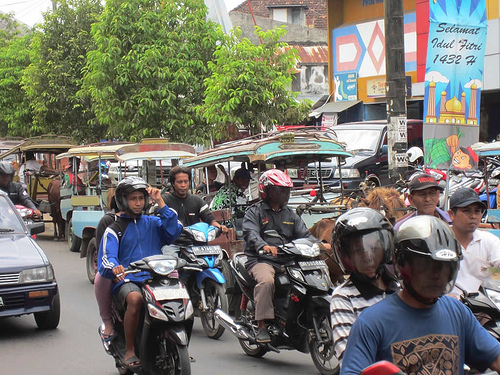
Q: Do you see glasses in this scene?
A: No, there are no glasses.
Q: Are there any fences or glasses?
A: No, there are no glasses or fences.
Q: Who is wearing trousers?
A: The man is wearing trousers.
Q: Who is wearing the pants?
A: The man is wearing trousers.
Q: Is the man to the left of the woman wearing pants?
A: Yes, the man is wearing pants.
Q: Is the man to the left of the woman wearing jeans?
A: No, the man is wearing pants.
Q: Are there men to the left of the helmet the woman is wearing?
A: Yes, there is a man to the left of the helmet.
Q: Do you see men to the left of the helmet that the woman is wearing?
A: Yes, there is a man to the left of the helmet.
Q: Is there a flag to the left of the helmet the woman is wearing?
A: No, there is a man to the left of the helmet.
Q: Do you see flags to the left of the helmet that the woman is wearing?
A: No, there is a man to the left of the helmet.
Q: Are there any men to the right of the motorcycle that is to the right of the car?
A: Yes, there is a man to the right of the motorcycle.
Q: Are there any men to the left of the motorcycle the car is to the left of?
A: No, the man is to the right of the motorcycle.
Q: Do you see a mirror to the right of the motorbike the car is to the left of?
A: No, there is a man to the right of the motorbike.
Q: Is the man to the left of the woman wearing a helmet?
A: Yes, the man is wearing a helmet.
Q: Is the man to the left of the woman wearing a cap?
A: No, the man is wearing a helmet.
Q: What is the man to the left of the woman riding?
A: The man is riding a motorcycle.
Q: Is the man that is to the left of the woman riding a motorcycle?
A: Yes, the man is riding a motorcycle.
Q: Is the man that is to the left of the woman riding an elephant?
A: No, the man is riding a motorcycle.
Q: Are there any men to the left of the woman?
A: Yes, there is a man to the left of the woman.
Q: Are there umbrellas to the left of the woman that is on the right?
A: No, there is a man to the left of the woman.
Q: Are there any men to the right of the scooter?
A: Yes, there is a man to the right of the scooter.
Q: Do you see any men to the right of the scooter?
A: Yes, there is a man to the right of the scooter.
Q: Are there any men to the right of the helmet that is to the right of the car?
A: Yes, there is a man to the right of the helmet.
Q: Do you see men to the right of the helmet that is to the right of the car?
A: Yes, there is a man to the right of the helmet.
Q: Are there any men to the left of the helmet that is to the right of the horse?
A: No, the man is to the right of the helmet.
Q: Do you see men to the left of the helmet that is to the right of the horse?
A: No, the man is to the right of the helmet.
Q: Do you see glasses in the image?
A: No, there are no glasses.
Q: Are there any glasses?
A: No, there are no glasses.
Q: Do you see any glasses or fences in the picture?
A: No, there are no glasses or fences.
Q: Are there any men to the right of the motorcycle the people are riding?
A: Yes, there is a man to the right of the motorbike.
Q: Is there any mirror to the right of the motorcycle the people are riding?
A: No, there is a man to the right of the motorbike.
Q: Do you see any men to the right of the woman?
A: Yes, there is a man to the right of the woman.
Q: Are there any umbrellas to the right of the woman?
A: No, there is a man to the right of the woman.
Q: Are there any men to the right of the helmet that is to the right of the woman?
A: Yes, there is a man to the right of the helmet.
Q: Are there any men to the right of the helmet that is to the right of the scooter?
A: Yes, there is a man to the right of the helmet.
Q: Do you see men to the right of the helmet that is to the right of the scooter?
A: Yes, there is a man to the right of the helmet.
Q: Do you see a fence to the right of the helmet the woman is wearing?
A: No, there is a man to the right of the helmet.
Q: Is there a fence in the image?
A: No, there are no fences.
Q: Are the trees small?
A: Yes, the trees are small.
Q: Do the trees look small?
A: Yes, the trees are small.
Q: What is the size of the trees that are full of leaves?
A: The trees are small.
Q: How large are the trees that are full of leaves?
A: The trees are small.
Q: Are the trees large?
A: No, the trees are small.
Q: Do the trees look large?
A: No, the trees are small.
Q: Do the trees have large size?
A: No, the trees are small.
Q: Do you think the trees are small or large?
A: The trees are small.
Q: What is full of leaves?
A: The trees are full of leaves.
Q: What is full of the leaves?
A: The trees are full of leaves.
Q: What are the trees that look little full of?
A: The trees are full of leaves.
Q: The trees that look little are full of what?
A: The trees are full of leaves.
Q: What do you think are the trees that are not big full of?
A: The trees are full of leaves.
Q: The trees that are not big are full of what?
A: The trees are full of leaves.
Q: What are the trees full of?
A: The trees are full of leaves.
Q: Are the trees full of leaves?
A: Yes, the trees are full of leaves.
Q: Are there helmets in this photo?
A: Yes, there is a helmet.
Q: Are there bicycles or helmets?
A: Yes, there is a helmet.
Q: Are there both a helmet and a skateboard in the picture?
A: No, there is a helmet but no skateboards.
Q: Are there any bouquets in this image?
A: No, there are no bouquets.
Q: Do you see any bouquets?
A: No, there are no bouquets.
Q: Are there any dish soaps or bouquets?
A: No, there are no bouquets or dish soaps.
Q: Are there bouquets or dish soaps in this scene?
A: No, there are no bouquets or dish soaps.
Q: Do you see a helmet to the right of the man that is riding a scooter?
A: Yes, there is a helmet to the right of the man.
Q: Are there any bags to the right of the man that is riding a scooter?
A: No, there is a helmet to the right of the man.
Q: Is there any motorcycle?
A: Yes, there is a motorcycle.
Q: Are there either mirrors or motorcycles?
A: Yes, there is a motorcycle.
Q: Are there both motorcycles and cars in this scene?
A: Yes, there are both a motorcycle and a car.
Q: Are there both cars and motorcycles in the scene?
A: Yes, there are both a motorcycle and a car.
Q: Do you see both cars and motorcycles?
A: Yes, there are both a motorcycle and a car.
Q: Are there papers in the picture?
A: No, there are no papers.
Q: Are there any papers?
A: No, there are no papers.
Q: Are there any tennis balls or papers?
A: No, there are no papers or tennis balls.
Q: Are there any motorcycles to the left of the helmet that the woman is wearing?
A: Yes, there is a motorcycle to the left of the helmet.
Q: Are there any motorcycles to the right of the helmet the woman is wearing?
A: No, the motorcycle is to the left of the helmet.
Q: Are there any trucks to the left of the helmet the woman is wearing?
A: No, there is a motorcycle to the left of the helmet.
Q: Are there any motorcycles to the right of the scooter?
A: Yes, there is a motorcycle to the right of the scooter.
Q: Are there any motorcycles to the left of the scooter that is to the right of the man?
A: No, the motorcycle is to the right of the scooter.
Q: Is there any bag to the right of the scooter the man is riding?
A: No, there is a motorcycle to the right of the scooter.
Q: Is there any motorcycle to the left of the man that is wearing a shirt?
A: Yes, there is a motorcycle to the left of the man.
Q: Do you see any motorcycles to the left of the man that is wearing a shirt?
A: Yes, there is a motorcycle to the left of the man.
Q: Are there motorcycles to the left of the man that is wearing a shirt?
A: Yes, there is a motorcycle to the left of the man.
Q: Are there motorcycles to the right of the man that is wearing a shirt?
A: No, the motorcycle is to the left of the man.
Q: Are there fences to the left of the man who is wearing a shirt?
A: No, there is a motorcycle to the left of the man.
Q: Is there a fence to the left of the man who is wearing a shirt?
A: No, there is a motorcycle to the left of the man.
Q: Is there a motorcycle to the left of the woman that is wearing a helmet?
A: Yes, there is a motorcycle to the left of the woman.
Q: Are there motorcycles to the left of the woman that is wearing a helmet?
A: Yes, there is a motorcycle to the left of the woman.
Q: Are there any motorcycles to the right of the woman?
A: No, the motorcycle is to the left of the woman.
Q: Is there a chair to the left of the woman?
A: No, there is a motorcycle to the left of the woman.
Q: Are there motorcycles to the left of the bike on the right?
A: Yes, there is a motorcycle to the left of the bike.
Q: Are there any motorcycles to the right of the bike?
A: No, the motorcycle is to the left of the bike.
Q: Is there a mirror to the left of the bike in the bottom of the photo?
A: No, there is a motorcycle to the left of the bike.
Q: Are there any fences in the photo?
A: No, there are no fences.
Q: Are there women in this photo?
A: Yes, there is a woman.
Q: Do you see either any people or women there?
A: Yes, there is a woman.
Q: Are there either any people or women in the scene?
A: Yes, there is a woman.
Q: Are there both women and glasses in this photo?
A: No, there is a woman but no glasses.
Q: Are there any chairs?
A: No, there are no chairs.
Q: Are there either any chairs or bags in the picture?
A: No, there are no chairs or bags.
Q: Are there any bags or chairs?
A: No, there are no chairs or bags.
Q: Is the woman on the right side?
A: Yes, the woman is on the right of the image.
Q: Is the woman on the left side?
A: No, the woman is on the right of the image.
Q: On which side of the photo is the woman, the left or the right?
A: The woman is on the right of the image.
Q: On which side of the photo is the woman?
A: The woman is on the right of the image.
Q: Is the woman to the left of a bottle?
A: No, the woman is to the left of the helmet.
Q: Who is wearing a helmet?
A: The woman is wearing a helmet.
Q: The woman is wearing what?
A: The woman is wearing a helmet.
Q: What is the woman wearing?
A: The woman is wearing a helmet.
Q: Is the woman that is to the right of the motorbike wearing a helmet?
A: Yes, the woman is wearing a helmet.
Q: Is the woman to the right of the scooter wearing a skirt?
A: No, the woman is wearing a helmet.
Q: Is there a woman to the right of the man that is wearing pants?
A: Yes, there is a woman to the right of the man.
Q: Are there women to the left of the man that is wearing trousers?
A: No, the woman is to the right of the man.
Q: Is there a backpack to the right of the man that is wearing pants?
A: No, there is a woman to the right of the man.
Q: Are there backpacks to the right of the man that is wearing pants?
A: No, there is a woman to the right of the man.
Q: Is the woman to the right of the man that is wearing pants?
A: Yes, the woman is to the right of the man.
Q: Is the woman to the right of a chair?
A: No, the woman is to the right of the man.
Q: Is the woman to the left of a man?
A: No, the woman is to the right of a man.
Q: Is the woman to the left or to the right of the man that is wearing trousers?
A: The woman is to the right of the man.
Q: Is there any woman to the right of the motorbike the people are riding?
A: Yes, there is a woman to the right of the motorbike.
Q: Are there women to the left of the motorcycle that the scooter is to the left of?
A: No, the woman is to the right of the motorbike.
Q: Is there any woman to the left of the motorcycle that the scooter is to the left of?
A: No, the woman is to the right of the motorbike.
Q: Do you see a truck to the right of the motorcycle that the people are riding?
A: No, there is a woman to the right of the motorbike.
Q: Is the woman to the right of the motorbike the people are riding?
A: Yes, the woman is to the right of the motorbike.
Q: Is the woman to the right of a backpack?
A: No, the woman is to the right of the motorbike.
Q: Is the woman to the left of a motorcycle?
A: No, the woman is to the right of a motorcycle.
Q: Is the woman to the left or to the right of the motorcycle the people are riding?
A: The woman is to the right of the motorcycle.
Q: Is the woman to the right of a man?
A: No, the woman is to the left of a man.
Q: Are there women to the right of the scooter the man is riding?
A: Yes, there is a woman to the right of the scooter.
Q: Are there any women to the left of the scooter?
A: No, the woman is to the right of the scooter.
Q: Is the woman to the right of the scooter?
A: Yes, the woman is to the right of the scooter.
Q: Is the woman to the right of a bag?
A: No, the woman is to the right of the scooter.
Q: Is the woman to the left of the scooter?
A: No, the woman is to the right of the scooter.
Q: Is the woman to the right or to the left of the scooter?
A: The woman is to the right of the scooter.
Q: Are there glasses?
A: No, there are no glasses.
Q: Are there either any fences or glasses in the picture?
A: No, there are no glasses or fences.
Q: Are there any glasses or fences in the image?
A: No, there are no glasses or fences.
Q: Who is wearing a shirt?
A: The man is wearing a shirt.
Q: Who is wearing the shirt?
A: The man is wearing a shirt.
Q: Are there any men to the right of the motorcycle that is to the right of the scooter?
A: Yes, there is a man to the right of the motorbike.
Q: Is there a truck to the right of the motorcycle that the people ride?
A: No, there is a man to the right of the motorbike.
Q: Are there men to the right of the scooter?
A: Yes, there is a man to the right of the scooter.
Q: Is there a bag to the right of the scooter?
A: No, there is a man to the right of the scooter.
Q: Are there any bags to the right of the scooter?
A: No, there is a man to the right of the scooter.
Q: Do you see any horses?
A: Yes, there is a horse.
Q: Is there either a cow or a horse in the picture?
A: Yes, there is a horse.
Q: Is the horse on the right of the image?
A: No, the horse is on the left of the image.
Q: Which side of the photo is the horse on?
A: The horse is on the left of the image.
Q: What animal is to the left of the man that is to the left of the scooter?
A: The animal is a horse.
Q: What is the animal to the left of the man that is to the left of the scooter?
A: The animal is a horse.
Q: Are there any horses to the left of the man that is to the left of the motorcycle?
A: Yes, there is a horse to the left of the man.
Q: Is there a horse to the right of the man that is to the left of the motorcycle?
A: No, the horse is to the left of the man.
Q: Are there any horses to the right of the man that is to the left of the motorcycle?
A: No, the horse is to the left of the man.